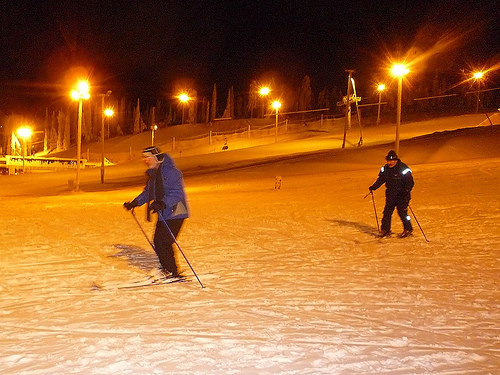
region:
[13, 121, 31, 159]
an overhead outdoor light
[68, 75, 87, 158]
an overhead outdoor light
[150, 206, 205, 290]
a black ski pole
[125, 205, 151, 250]
a black ski pole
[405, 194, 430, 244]
a black ski pole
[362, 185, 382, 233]
a black ski pole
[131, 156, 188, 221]
a blue winter coat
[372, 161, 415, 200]
a black and white winter coat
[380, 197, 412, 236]
a pair of black snow pants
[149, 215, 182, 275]
a pair of black snow pants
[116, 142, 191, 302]
person skiing in snow on mountain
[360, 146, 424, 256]
person skiing in snow on mountain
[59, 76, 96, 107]
yellow light on pole at might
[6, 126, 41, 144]
yellow light on pole at might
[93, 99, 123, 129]
yellow light on pole at might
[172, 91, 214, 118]
yellow light on pole at might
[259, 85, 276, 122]
yellow light on pole at might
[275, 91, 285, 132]
yellow light on pole at might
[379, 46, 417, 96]
yellow light on pole at might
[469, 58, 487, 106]
yellow light on pole at might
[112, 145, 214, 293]
a snow skier going downhill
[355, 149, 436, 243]
a snow skier going downhill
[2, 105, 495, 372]
a snowy ski slope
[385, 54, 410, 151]
an overhead outdoor light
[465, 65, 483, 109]
an overhead outdoor light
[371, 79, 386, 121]
an overhead outdoor light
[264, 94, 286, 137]
an overhead outdoor light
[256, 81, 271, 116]
an overhead outdoor light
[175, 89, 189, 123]
an overhead outdoor light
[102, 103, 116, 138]
an overhead outdoor light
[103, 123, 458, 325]
Two persons snowboarding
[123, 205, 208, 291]
The person holding the ski pole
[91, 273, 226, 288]
White color snowboard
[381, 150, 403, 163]
A person wearing black color hat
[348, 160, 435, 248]
A person wearing black and white color jacket & jean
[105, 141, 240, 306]
A person wearing blue color jacket and black jean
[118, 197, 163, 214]
A person wearing black color gloves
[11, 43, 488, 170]
A metal post with orange color lamps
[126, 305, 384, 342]
White color snow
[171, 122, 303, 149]
Fencing near the lamp post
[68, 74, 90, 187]
Lights shining on light pole.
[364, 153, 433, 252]
Man skiing in snow.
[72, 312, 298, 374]
Tracks in the snow.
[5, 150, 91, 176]
Railing on walkway over the ground.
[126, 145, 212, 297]
Person wearing blue jacket.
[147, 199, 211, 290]
Blue ski poles in man's hand.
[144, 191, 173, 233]
Black glove on hand.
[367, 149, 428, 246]
Black jacket with white reflective material.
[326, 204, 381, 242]
Shadow of skier on the ground.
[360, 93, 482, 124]
Fence in the background.